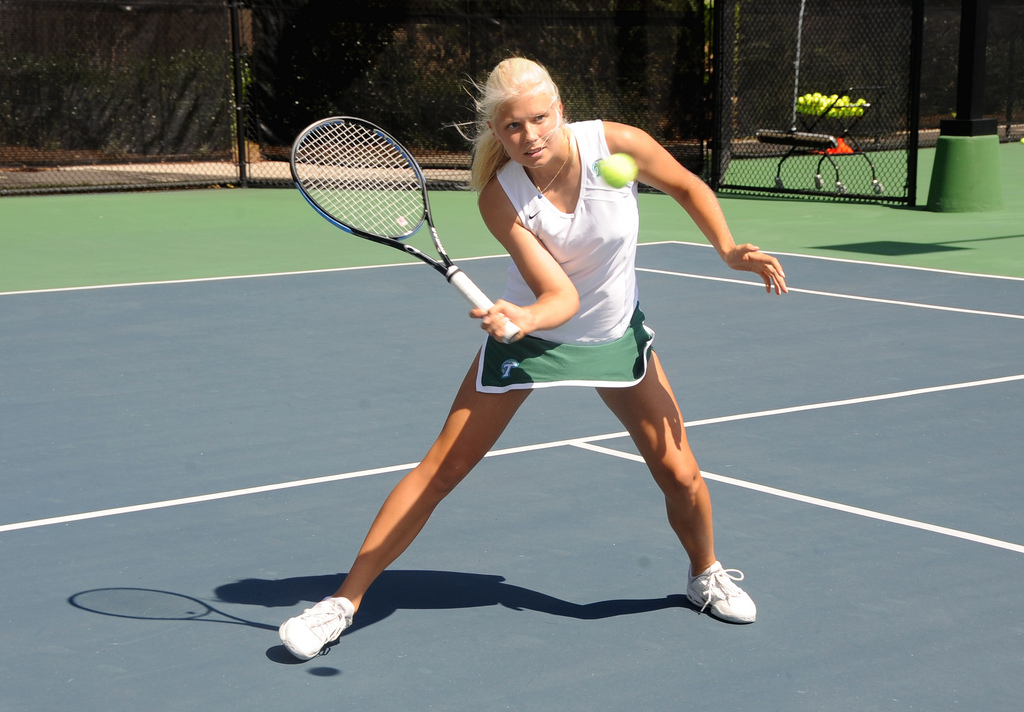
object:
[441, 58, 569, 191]
hair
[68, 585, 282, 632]
shadow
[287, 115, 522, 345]
racket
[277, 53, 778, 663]
girl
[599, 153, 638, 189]
ball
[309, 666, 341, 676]
shadow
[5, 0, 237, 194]
fence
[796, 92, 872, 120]
tennis balls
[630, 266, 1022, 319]
line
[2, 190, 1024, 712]
tennis court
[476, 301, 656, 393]
skirt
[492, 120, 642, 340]
shirt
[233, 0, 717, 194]
fence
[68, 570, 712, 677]
shadow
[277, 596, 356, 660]
shoe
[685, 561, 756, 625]
sneaker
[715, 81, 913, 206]
cart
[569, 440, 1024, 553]
line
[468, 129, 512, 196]
ponytail